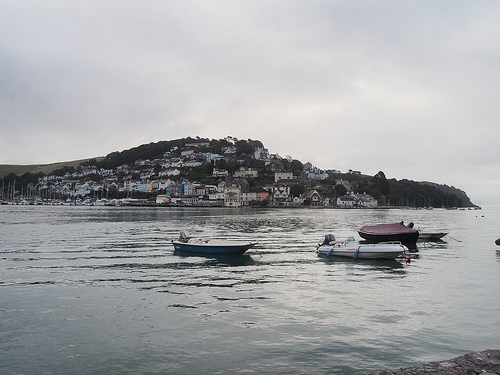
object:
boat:
[169, 230, 258, 255]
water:
[0, 202, 499, 374]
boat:
[316, 232, 410, 265]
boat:
[357, 218, 464, 243]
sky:
[0, 2, 499, 202]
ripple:
[7, 272, 253, 290]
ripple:
[17, 257, 216, 273]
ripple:
[167, 289, 270, 306]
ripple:
[346, 263, 393, 272]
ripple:
[260, 255, 326, 270]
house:
[212, 167, 228, 178]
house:
[246, 167, 258, 178]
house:
[224, 189, 241, 206]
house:
[180, 147, 194, 160]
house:
[210, 153, 220, 160]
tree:
[48, 168, 63, 176]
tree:
[59, 167, 68, 177]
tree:
[62, 166, 71, 172]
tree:
[88, 159, 98, 166]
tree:
[103, 157, 110, 166]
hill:
[0, 135, 477, 207]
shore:
[383, 347, 500, 375]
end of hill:
[350, 168, 476, 209]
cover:
[358, 221, 420, 240]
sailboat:
[19, 182, 34, 205]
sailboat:
[23, 186, 35, 207]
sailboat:
[43, 186, 53, 207]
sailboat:
[47, 190, 54, 205]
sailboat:
[63, 192, 71, 205]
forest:
[389, 179, 455, 209]